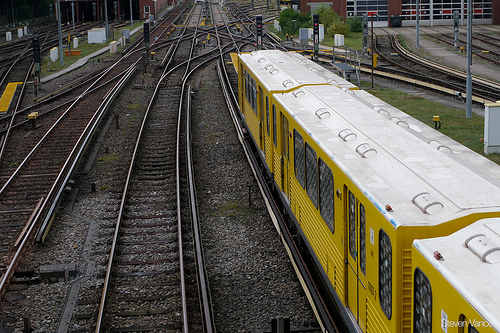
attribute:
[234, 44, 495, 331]
train — yellow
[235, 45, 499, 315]
car — passenger car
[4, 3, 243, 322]
train tracks — set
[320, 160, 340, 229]
window — passenger's, train's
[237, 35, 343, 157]
car — white, yellow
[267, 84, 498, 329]
car — yellow, white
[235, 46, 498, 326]
roof — white, painted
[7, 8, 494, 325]
rails — crossing, many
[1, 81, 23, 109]
paint — yellow, red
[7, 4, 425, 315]
railroad tracks — made, steel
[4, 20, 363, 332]
tracks — crossing, criss-crossing, trainless, metal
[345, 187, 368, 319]
doors — yellow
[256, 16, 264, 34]
lights — red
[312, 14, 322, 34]
lights — red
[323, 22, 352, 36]
bush — green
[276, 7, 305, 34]
bush — green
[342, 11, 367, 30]
bush — green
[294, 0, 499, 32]
building — brick, red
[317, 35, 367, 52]
grass — gree, green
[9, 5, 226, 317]
gravel — gray, red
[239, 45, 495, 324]
top — white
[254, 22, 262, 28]
light — red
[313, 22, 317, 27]
light — red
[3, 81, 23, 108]
strip — yellow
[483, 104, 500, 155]
box — white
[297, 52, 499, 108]
slat — wooden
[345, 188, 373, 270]
windows — checkered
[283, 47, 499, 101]
slate — wood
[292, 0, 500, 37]
train station — close